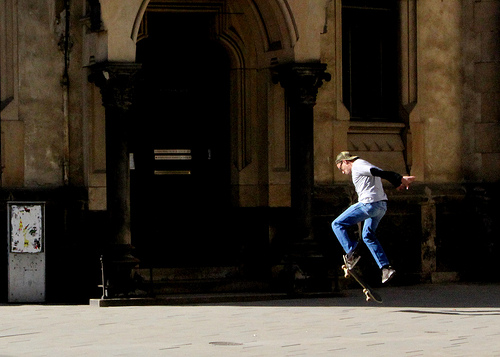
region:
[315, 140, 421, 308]
a skater is jumping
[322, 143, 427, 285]
skater wears blue jeans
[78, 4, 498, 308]
a skater in front an old building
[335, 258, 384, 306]
the skateboard is color black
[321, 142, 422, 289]
the skater is looking down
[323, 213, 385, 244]
knees are bend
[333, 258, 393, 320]
skateboard is above the ground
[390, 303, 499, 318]
a shadow cast on the ground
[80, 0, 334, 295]
two columns on side a door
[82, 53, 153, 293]
column is color brown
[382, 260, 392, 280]
shoe on the foot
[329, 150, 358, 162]
hat on the head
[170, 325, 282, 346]
the ground is concrete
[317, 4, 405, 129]
window of the building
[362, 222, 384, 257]
pants on the leg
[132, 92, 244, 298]
door of the building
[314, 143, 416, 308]
the man is jumping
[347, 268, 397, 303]
skateboard in the air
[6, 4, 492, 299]
skateboarder in front of building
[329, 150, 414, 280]
skater jumping in the air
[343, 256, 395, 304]
tilted airborne skateboard under feet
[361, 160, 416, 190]
arms extended behind back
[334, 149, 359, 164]
backwards hat on head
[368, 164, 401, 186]
long black sleeves on arm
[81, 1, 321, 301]
arched doorway of building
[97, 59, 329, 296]
two columns in front of door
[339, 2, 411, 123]
dark window on building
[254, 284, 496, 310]
shadow on paved surface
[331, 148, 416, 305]
A skater leaping with his board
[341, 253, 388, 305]
A skateboard in midair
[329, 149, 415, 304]
A man in a hat performing on a skateboard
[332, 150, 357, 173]
A hat being worn backwards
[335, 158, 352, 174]
A man with sunglasses on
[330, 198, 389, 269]
A pair of blue jeans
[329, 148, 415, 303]
A man in a hat riding a skateboard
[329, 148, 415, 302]
A man in a gray shirt jumping with his skateboard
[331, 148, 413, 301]
A man in shades flipping his skateboard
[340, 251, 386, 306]
A skateboard coming off the ground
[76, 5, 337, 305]
An entrance to a building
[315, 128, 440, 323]
A man jumping on a skateboard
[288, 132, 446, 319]
A man using a skateboard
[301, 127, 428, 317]
A man wearing a green hat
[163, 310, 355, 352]
A gray concrete ground surface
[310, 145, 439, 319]
A man wearing blue jeans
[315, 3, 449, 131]
A large window on a building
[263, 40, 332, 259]
A pillar at the entrance of a building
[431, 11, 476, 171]
A brown stone wall of a building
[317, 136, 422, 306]
A man wearing a gray t-shirt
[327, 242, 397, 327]
a skateboard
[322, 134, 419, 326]
a man skateboarding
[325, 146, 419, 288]
man in air over skateboard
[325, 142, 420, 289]
man is doing tricks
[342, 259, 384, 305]
skateboard is in air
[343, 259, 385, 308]
man's skateboard is black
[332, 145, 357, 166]
man wearing baseball cap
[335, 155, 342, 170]
man wearing eye glasses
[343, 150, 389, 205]
man wearing gray shirt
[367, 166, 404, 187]
black long sleeves shirt under gray shirt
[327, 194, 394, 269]
man wearing blue jeans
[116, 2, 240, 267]
large door behind steps